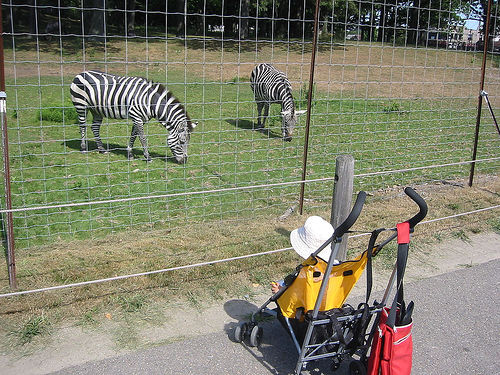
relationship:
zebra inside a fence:
[71, 72, 195, 165] [0, 0, 500, 254]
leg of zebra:
[132, 119, 155, 162] [71, 72, 195, 165]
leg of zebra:
[75, 106, 92, 152] [71, 72, 195, 165]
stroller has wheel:
[234, 184, 430, 373] [234, 322, 264, 347]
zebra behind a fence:
[71, 72, 195, 165] [4, 6, 500, 275]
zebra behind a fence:
[249, 63, 305, 142] [4, 6, 500, 275]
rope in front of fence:
[0, 148, 499, 218] [4, 6, 500, 275]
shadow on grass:
[61, 139, 174, 162] [3, 73, 498, 256]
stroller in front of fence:
[234, 184, 430, 373] [0, 0, 500, 254]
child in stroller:
[268, 217, 339, 304] [234, 184, 430, 373]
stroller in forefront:
[234, 184, 430, 373] [89, 203, 455, 373]